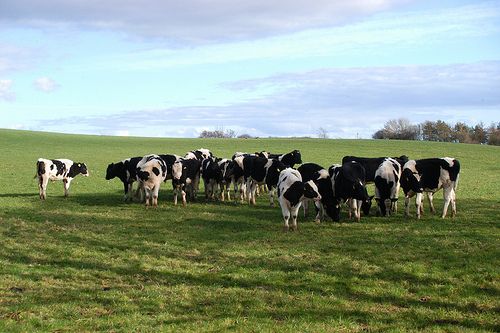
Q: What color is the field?
A: Green.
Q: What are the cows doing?
A: Grazing.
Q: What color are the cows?
A: White and black.